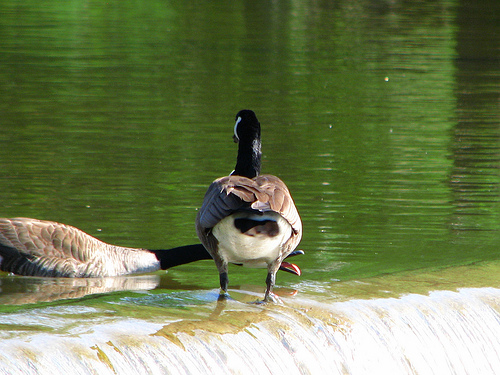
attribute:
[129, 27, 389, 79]
water — green, flowing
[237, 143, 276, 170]
neck — black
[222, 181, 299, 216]
feathers — brown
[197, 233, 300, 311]
goose — standing